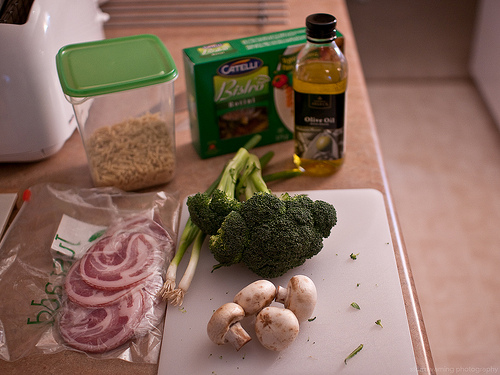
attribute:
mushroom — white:
[204, 298, 254, 353]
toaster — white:
[4, 2, 108, 164]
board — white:
[184, 189, 445, 356]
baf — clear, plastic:
[27, 212, 189, 366]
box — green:
[184, 28, 348, 145]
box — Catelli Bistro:
[119, 15, 396, 187]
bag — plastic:
[0, 177, 194, 372]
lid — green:
[53, 31, 176, 95]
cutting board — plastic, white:
[155, 186, 424, 373]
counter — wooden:
[6, 9, 439, 372]